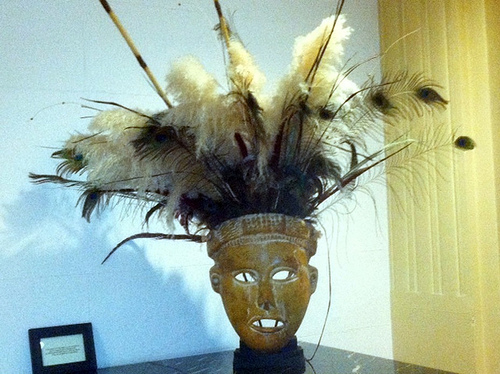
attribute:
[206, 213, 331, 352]
sculpture — face, mask, brown, weird, large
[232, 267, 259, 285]
eyehole — white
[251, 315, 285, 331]
mouthhole — white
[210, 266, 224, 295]
ear — brown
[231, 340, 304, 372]
stand — black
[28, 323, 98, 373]
sign — framed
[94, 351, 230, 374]
table — marble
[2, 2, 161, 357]
wall — white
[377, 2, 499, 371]
wall — yellow, wood